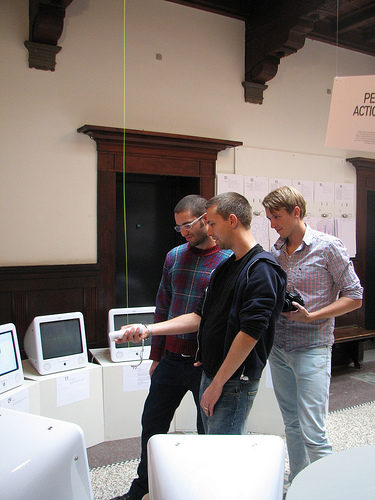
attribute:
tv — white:
[105, 306, 157, 360]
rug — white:
[104, 403, 371, 489]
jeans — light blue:
[247, 343, 356, 434]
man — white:
[108, 189, 246, 499]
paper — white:
[54, 369, 90, 404]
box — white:
[23, 357, 106, 448]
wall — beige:
[1, 0, 373, 265]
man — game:
[107, 192, 287, 357]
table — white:
[24, 345, 116, 460]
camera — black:
[279, 284, 305, 315]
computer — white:
[92, 286, 183, 367]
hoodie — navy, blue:
[197, 242, 291, 382]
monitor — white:
[2, 321, 42, 402]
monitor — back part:
[109, 296, 167, 371]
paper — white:
[58, 369, 91, 403]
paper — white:
[122, 361, 153, 390]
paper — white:
[263, 363, 273, 386]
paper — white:
[5, 386, 27, 414]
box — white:
[102, 361, 172, 437]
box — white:
[246, 355, 285, 436]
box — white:
[41, 375, 102, 443]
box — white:
[2, 382, 43, 418]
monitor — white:
[25, 311, 138, 409]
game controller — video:
[106, 323, 149, 344]